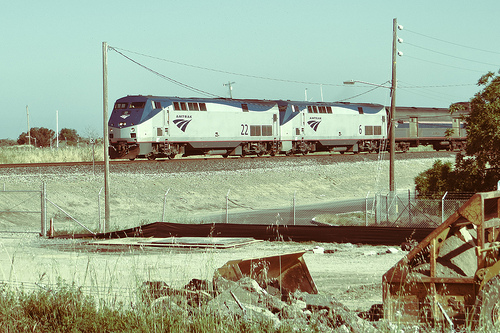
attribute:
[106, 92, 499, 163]
train — white, blue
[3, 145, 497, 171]
tracks — steel, brown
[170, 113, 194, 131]
logo — blue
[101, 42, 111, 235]
pole — wooden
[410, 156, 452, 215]
shrub — small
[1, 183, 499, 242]
fence — metal, high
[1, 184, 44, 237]
gate — closed, metal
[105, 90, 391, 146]
engine — blue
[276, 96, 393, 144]
train — number 6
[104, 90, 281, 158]
train — number 22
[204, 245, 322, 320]
bin — metal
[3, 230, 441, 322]
road — paved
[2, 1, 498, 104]
sky — blue